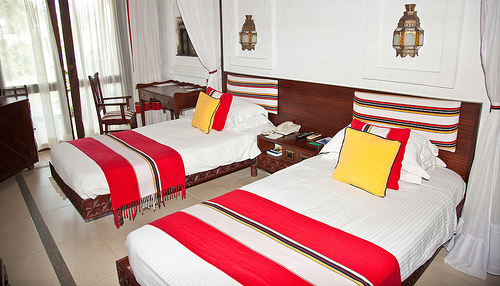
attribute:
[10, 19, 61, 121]
curtains — white, sheer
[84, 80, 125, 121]
chair — brown, wooden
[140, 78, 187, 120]
desk — brown, wooden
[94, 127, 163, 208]
blanket — red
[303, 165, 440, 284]
bedspread — white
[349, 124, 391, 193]
pillow — yellow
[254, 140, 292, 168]
table — brown, wooden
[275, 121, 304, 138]
phone — white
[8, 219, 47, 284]
floor — white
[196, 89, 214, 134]
pillow — yellow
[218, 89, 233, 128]
pillow — red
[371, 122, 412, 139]
pillow — white, red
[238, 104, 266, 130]
pillow — white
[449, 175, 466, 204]
sheet — white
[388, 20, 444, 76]
lamp — brown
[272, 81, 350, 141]
headboard — brown, wooden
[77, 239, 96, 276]
tile — white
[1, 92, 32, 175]
dresser — brown, wooden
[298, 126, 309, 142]
remote — black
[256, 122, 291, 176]
stand — wooden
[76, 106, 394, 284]
beds — twin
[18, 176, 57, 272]
stripe — gray